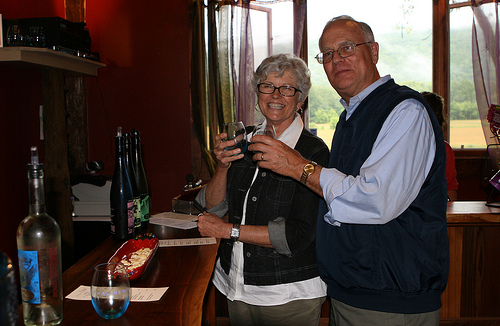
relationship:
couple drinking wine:
[194, 8, 455, 324] [213, 115, 278, 185]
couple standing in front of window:
[194, 8, 455, 324] [194, 5, 499, 165]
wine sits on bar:
[13, 146, 61, 323] [20, 207, 220, 326]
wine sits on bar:
[109, 128, 139, 239] [20, 207, 220, 326]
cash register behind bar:
[61, 160, 118, 223] [52, 194, 237, 324]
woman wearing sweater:
[195, 54, 332, 326] [213, 127, 330, 283]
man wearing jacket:
[247, 14, 449, 325] [313, 78, 448, 313]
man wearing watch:
[245, 9, 478, 303] [300, 161, 319, 185]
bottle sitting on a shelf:
[97, 127, 151, 242] [34, 220, 229, 323]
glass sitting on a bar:
[89, 261, 131, 324] [20, 207, 220, 326]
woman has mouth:
[219, 67, 331, 207] [263, 97, 285, 115]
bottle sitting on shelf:
[11, 139, 55, 324] [52, 231, 219, 324]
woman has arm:
[195, 54, 332, 326] [193, 208, 316, 255]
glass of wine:
[220, 116, 249, 167] [213, 102, 262, 162]